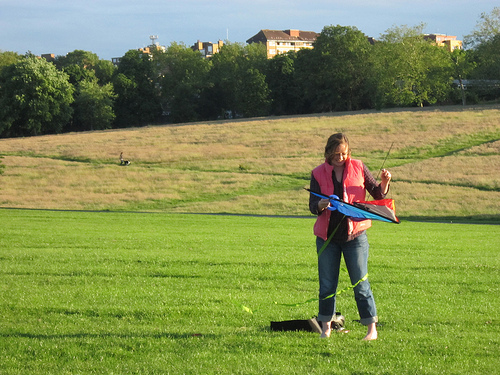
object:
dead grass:
[370, 154, 499, 190]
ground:
[0, 106, 494, 373]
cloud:
[0, 0, 499, 61]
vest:
[313, 157, 372, 241]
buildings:
[245, 29, 323, 60]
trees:
[63, 62, 121, 132]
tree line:
[0, 6, 499, 139]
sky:
[0, 0, 499, 64]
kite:
[303, 186, 402, 223]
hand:
[378, 168, 392, 184]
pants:
[317, 233, 379, 325]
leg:
[316, 236, 343, 321]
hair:
[323, 133, 350, 166]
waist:
[317, 213, 367, 234]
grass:
[0, 208, 499, 373]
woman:
[308, 132, 393, 340]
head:
[322, 133, 349, 168]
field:
[0, 106, 499, 373]